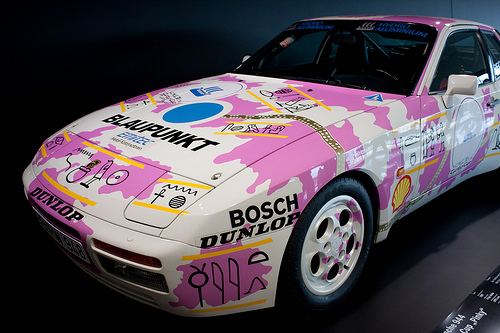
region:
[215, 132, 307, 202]
Pink color on car.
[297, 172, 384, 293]
Pink and white rim on tire.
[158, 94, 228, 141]
Blue circle on car.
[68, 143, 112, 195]
Stick symbols on car.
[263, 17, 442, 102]
Front windshield on car.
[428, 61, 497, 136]
White painted side mirror on car.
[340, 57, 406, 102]
Steering wheel on car.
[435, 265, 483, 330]
Black strip on floor.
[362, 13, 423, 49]
Blue writing on window.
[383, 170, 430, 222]
Shell logo on side of car.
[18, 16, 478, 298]
this is a car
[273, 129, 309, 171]
the car is pink in color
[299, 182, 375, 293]
this is the wheel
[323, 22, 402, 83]
the screen is clear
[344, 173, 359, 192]
the wheel is black in color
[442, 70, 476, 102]
this is a side mirror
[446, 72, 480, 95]
the side mirror is white in color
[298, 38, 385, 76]
the screen is tinted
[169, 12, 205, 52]
this is the wall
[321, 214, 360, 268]
the rim is white in color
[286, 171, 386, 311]
Black tire with silver rim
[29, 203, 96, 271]
White license plate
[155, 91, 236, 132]
Large blue circle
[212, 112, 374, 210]
Pink paint splotch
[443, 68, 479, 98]
One white automobile mirror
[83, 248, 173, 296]
One automobile headlight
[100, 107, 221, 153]
The word "BLAUPUNKT" in black letters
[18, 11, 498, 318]
White racecar with pink paint splotches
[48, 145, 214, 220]
Car graffiti on car hood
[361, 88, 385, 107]
Blue triangle with white design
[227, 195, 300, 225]
a black BOSCH word on the car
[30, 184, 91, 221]
a black DUNLOP word on the car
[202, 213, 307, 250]
a black DUNLOP word on the car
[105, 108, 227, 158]
a black BLAUPUNKT word on the car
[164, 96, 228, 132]
a large blue circle on the car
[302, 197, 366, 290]
a pink and white hubcap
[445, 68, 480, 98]
a white car mirror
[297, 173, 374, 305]
a black rubber car tire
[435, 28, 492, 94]
a car window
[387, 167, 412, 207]
a red and white shell logo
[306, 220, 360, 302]
part of a wheel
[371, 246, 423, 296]
part of a shade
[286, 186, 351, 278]
part of a wheel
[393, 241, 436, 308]
part of a carpet